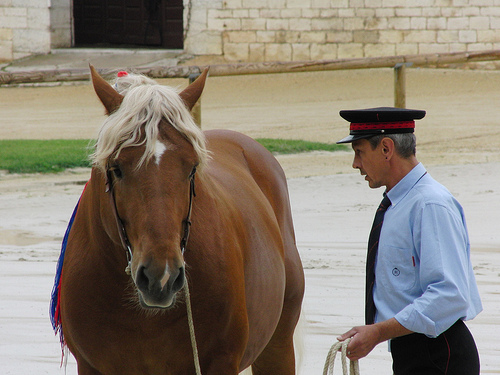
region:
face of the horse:
[91, 87, 217, 317]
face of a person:
[323, 89, 443, 189]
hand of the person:
[323, 315, 395, 367]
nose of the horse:
[129, 260, 206, 313]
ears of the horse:
[64, 50, 219, 117]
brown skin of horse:
[201, 237, 241, 322]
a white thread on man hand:
[302, 323, 372, 370]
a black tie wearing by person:
[363, 216, 391, 346]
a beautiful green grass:
[8, 117, 416, 199]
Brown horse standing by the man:
[46, 58, 286, 370]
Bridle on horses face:
[98, 156, 210, 339]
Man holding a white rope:
[295, 307, 357, 369]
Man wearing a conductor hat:
[328, 95, 444, 160]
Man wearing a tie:
[350, 190, 396, 324]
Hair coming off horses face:
[120, 269, 200, 325]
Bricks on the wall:
[220, 10, 313, 75]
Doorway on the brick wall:
[57, 0, 217, 65]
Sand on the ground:
[288, 166, 366, 274]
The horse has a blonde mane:
[101, 73, 211, 188]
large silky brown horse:
[37, 55, 304, 370]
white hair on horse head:
[66, 55, 236, 195]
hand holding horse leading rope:
[311, 317, 372, 371]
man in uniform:
[323, 93, 461, 373]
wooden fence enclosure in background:
[290, 45, 478, 97]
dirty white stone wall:
[222, 11, 450, 44]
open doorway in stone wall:
[50, 5, 195, 55]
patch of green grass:
[11, 125, 347, 180]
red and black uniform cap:
[325, 95, 430, 151]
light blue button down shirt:
[346, 163, 485, 350]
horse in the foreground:
[30, 63, 299, 374]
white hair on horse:
[125, 84, 189, 144]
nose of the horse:
[111, 233, 213, 353]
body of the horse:
[194, 194, 315, 305]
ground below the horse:
[312, 238, 354, 310]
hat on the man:
[318, 91, 446, 163]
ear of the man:
[374, 133, 401, 172]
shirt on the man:
[343, 173, 465, 306]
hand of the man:
[313, 301, 415, 365]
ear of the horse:
[176, 78, 217, 113]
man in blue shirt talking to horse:
[76, 52, 474, 321]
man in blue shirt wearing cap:
[313, 107, 440, 204]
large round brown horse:
[56, 70, 309, 358]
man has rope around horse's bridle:
[153, 255, 376, 365]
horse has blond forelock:
[67, 61, 214, 178]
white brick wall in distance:
[194, 14, 477, 75]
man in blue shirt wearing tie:
[338, 169, 393, 317]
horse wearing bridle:
[96, 142, 206, 313]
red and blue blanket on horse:
[46, 154, 94, 355]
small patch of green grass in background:
[20, 85, 334, 177]